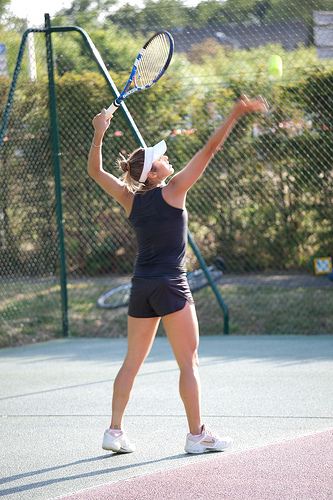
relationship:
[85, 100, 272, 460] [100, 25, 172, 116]
female swinging tennis racket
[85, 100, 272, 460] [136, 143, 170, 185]
female wearing visor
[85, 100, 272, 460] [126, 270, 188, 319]
female wearing skirt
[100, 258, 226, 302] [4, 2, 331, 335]
bicycle laying beside fencing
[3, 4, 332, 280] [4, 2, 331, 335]
trees behind fencing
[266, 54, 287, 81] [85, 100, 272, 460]
tennis ball thrown by female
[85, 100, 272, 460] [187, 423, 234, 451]
female wearing shoe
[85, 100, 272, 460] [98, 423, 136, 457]
female wearing shoe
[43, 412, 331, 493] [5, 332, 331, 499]
line on tennis court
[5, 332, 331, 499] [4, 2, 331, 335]
tennis court inside fencing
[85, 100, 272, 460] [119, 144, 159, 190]
female has hair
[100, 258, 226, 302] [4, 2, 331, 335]
bicycle outside fencing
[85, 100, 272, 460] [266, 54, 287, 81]
female serving tennis ball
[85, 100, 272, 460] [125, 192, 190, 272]
female wearing tank top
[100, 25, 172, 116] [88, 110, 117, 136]
tennis racket in hand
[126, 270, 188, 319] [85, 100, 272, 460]
skirt of female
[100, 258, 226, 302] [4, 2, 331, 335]
bicycle behind fencing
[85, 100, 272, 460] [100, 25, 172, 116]
female holding tennis racket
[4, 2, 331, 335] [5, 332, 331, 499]
fencing around tennis court